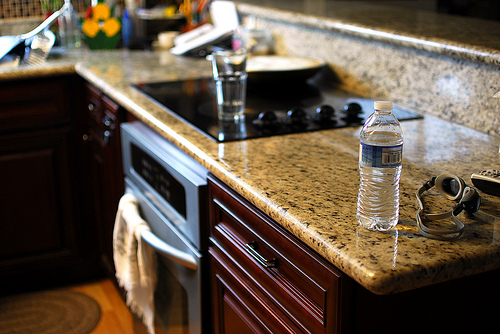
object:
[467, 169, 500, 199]
remote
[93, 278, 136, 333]
wood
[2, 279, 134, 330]
floor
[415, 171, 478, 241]
goggles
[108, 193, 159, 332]
towel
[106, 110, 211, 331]
door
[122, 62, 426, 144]
stove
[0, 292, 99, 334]
rug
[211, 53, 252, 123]
glass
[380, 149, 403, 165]
barcode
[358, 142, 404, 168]
label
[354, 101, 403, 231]
bottle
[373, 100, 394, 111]
cap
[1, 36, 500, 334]
counter